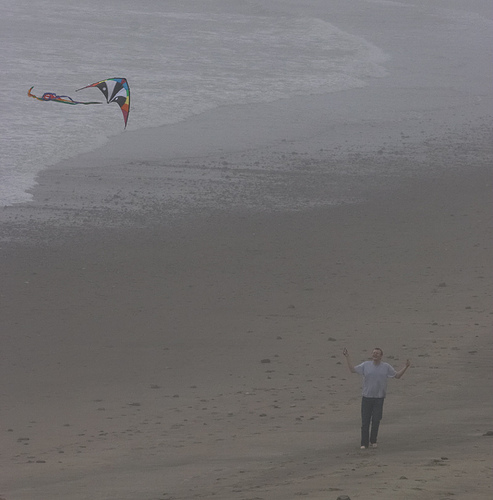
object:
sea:
[0, 0, 383, 210]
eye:
[374, 352, 380, 354]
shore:
[0, 0, 493, 500]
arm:
[390, 366, 409, 379]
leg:
[361, 408, 370, 446]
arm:
[347, 357, 363, 374]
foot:
[361, 442, 367, 449]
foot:
[372, 442, 378, 449]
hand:
[343, 347, 349, 355]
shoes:
[360, 443, 376, 450]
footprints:
[16, 266, 489, 466]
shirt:
[354, 359, 397, 398]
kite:
[28, 77, 130, 130]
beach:
[1, 2, 493, 500]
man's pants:
[361, 397, 384, 445]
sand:
[0, 0, 492, 500]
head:
[372, 347, 382, 360]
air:
[206, 23, 416, 126]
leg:
[370, 408, 383, 441]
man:
[343, 346, 410, 450]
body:
[362, 361, 387, 396]